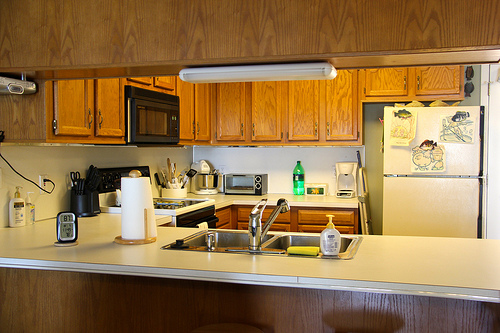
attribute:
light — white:
[179, 62, 339, 84]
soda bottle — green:
[293, 160, 306, 195]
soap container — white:
[320, 214, 343, 256]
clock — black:
[56, 210, 79, 243]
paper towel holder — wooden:
[114, 168, 158, 244]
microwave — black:
[124, 84, 181, 144]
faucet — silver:
[249, 197, 292, 251]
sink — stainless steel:
[160, 228, 366, 260]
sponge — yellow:
[287, 245, 321, 256]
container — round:
[161, 185, 187, 198]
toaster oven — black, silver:
[221, 171, 269, 196]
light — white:
[173, 59, 341, 86]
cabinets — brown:
[220, 92, 352, 150]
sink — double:
[180, 210, 349, 261]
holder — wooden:
[112, 168, 156, 244]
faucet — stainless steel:
[240, 189, 298, 267]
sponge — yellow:
[280, 236, 317, 264]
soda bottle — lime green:
[290, 160, 305, 198]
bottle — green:
[289, 160, 306, 196]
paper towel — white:
[115, 175, 160, 242]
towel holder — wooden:
[112, 167, 157, 248]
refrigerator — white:
[384, 102, 484, 235]